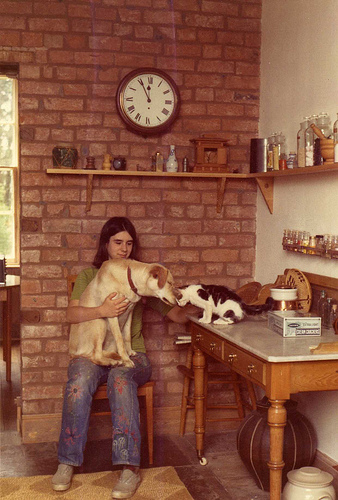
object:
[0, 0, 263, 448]
wall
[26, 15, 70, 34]
brick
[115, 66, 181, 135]
clock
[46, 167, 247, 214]
shelf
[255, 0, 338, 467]
wall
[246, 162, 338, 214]
shelf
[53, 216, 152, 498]
girl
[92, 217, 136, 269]
hair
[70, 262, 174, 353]
shirt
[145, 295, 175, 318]
sleeve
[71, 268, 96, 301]
sleeve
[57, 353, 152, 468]
jeans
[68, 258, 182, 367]
dog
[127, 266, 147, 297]
collar